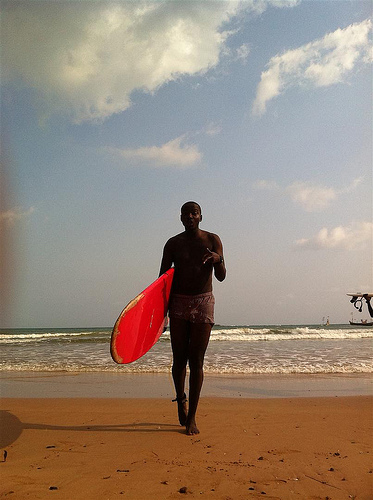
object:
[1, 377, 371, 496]
ground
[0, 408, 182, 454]
shadow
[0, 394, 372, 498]
sand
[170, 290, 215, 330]
shorts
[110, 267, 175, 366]
surf board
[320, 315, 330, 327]
people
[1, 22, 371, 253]
cloud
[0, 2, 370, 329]
sky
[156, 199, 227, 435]
dark skin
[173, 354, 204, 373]
knees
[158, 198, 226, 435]
man